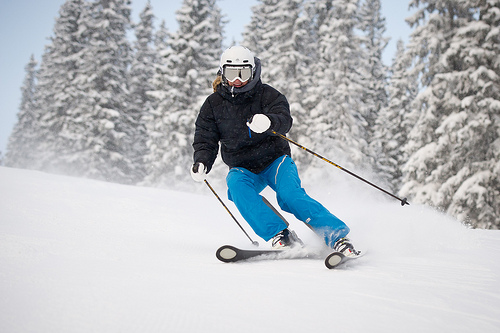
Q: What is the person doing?
A: Skiing.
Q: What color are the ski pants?
A: Blue.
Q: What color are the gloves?
A: White.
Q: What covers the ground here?
A: Snow.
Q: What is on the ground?
A: Snow.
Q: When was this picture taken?
A: Winter.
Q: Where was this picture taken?
A: Ski slope.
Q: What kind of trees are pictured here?
A: Pine trees.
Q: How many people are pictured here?
A: One.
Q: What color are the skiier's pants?
A: Blue.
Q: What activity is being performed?
A: Skiing.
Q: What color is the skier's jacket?
A: Black.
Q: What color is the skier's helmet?
A: White.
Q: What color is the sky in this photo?
A: Blue.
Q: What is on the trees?
A: Snow.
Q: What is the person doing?
A: Skiing.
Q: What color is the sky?
A: Blue.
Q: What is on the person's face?
A: Goggles.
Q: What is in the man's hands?
A: Ski Poles.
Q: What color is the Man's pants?
A: Blue.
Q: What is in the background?
A: Trees.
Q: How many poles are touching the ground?
A: One.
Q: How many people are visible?
A: 1.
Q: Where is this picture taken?
A: Mountainside.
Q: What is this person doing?
A: Skiing.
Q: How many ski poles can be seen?
A: 2.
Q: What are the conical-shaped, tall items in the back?
A: Evergreens.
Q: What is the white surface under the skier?
A: Snow.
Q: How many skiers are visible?
A: One.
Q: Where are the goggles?
A: On the skier's face.